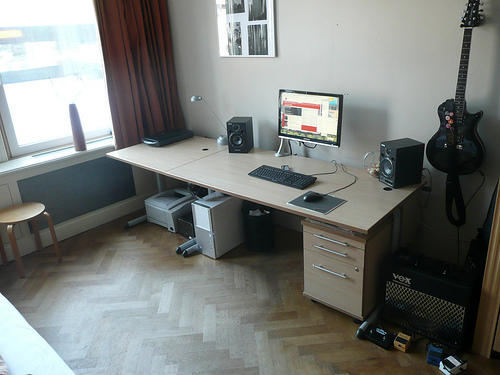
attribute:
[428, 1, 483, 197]
guitar — black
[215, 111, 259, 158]
speaker — black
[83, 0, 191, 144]
curtain — brown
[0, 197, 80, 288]
stool — wooden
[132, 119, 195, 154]
scanner — black